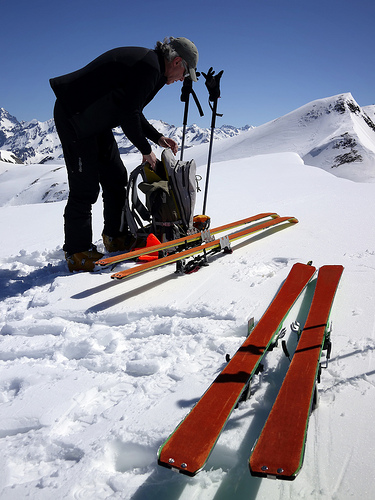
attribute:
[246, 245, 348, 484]
ski — red, auburn, orange, wood, wooden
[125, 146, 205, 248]
backpack — gray, grey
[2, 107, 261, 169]
mountain — snow covered, snowy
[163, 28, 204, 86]
hat — grey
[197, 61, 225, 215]
pole — black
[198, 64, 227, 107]
glove — black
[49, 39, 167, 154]
jacket — dark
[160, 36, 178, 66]
hair — gray, grey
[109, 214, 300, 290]
ski — upside down